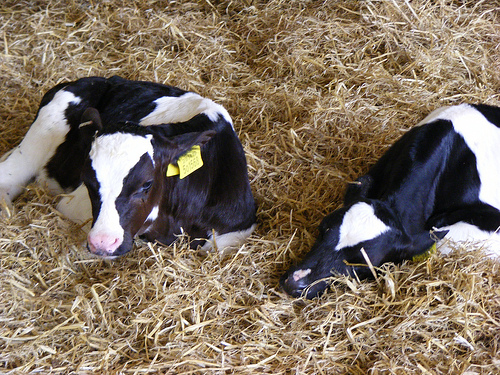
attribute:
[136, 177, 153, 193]
eye — dark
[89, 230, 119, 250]
nose — pink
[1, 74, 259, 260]
cow — resting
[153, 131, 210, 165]
ear — black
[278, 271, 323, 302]
nose — black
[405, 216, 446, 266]
ear — black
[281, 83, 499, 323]
cow — black, white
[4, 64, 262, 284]
cow — resting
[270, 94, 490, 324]
cow — sleeping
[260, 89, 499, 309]
cow — sleeping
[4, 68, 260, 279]
calf — black-and-white, black, white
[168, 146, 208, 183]
tag — yellow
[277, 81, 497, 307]
calf — black-and-white, black, white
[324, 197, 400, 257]
triangle — white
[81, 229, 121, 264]
nose — soft pink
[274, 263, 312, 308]
nose — soft black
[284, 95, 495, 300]
calf — laying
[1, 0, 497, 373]
straw — yellow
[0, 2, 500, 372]
straw pile — huge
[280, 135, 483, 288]
calf — black, white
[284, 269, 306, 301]
nose — black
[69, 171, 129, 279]
calf — black , white 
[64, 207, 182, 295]
nose — pink 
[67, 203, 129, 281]
nose — pink 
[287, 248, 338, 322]
nose — black 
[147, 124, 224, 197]
tag — yellow 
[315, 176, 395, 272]
spot — white 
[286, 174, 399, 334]
nose — black 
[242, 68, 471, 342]
cow — black , white 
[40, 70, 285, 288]
cow — white , black 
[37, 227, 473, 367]
straw — yellow 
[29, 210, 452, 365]
straw — yellow 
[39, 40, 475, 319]
cows — black , white 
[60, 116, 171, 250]
head — black 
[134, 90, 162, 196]
line — white 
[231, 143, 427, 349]
head — black 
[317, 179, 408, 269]
diamond — small , white 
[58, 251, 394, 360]
straw — yellow 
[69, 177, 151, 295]
nose — pink , big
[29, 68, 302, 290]
cow — white 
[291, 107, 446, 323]
cow — white , black 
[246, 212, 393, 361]
nose — black , big 